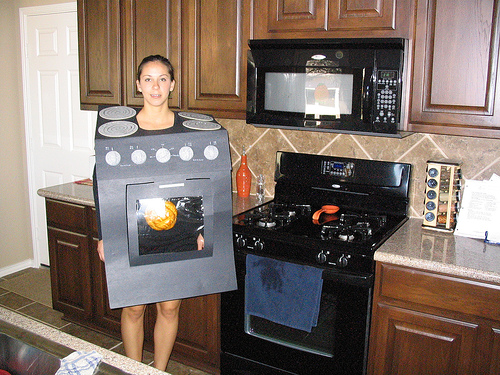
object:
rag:
[57, 349, 100, 374]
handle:
[316, 250, 327, 264]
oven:
[221, 150, 411, 375]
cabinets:
[74, 0, 250, 119]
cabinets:
[403, 0, 498, 142]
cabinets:
[45, 195, 222, 372]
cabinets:
[365, 260, 498, 373]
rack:
[236, 250, 373, 288]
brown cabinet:
[372, 266, 499, 374]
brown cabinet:
[406, 0, 499, 137]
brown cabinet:
[261, 0, 402, 37]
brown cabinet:
[182, 0, 247, 116]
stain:
[259, 262, 287, 293]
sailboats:
[426, 160, 464, 232]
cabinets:
[247, 0, 400, 41]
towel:
[242, 252, 327, 335]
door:
[124, 178, 213, 267]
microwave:
[245, 38, 413, 136]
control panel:
[370, 72, 399, 129]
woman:
[89, 54, 233, 367]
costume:
[94, 109, 233, 243]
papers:
[449, 172, 500, 243]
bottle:
[237, 153, 252, 197]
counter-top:
[37, 176, 499, 280]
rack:
[401, 157, 482, 234]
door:
[17, 3, 97, 263]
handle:
[336, 254, 349, 269]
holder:
[478, 225, 484, 240]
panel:
[127, 182, 212, 257]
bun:
[144, 198, 179, 234]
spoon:
[312, 204, 338, 220]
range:
[235, 186, 392, 256]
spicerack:
[418, 162, 462, 236]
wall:
[0, 0, 494, 373]